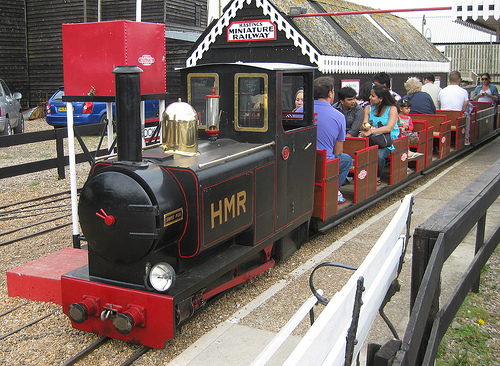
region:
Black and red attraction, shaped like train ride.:
[15, 0, 497, 339]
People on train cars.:
[312, 74, 499, 214]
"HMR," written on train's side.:
[191, 166, 279, 251]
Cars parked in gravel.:
[0, 81, 97, 192]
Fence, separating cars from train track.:
[0, 118, 166, 180]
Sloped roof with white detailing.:
[257, 0, 457, 84]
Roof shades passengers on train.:
[262, 0, 468, 208]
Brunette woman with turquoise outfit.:
[367, 81, 400, 155]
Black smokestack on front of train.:
[109, 65, 158, 196]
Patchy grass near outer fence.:
[440, 255, 487, 365]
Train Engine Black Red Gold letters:
[9, 59, 317, 346]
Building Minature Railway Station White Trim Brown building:
[177, 4, 455, 159]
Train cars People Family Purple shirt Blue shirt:
[282, 69, 409, 223]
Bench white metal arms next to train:
[147, 184, 439, 362]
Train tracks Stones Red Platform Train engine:
[2, 192, 160, 360]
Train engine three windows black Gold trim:
[173, 49, 324, 253]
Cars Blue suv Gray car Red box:
[0, 52, 181, 153]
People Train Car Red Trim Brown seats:
[393, 64, 498, 171]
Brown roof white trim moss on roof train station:
[267, 2, 459, 74]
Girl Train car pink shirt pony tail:
[349, 64, 463, 182]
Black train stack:
[103, 53, 160, 155]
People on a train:
[301, 55, 496, 149]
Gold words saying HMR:
[200, 177, 257, 232]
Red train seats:
[310, 112, 476, 217]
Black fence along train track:
[402, 157, 497, 354]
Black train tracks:
[0, 180, 85, 365]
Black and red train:
[66, 62, 316, 362]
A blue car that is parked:
[41, 80, 118, 140]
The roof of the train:
[160, 0, 460, 70]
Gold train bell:
[153, 93, 208, 158]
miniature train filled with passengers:
[60, 62, 499, 345]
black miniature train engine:
[60, 60, 318, 347]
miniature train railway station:
[182, 2, 452, 102]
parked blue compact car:
[47, 87, 167, 125]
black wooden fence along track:
[375, 157, 499, 364]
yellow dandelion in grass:
[450, 313, 499, 350]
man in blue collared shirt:
[290, 76, 351, 206]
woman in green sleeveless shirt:
[362, 85, 399, 177]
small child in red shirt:
[394, 98, 420, 147]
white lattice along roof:
[187, 0, 454, 70]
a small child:
[396, 102, 411, 127]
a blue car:
[44, 82, 169, 125]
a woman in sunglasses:
[471, 70, 498, 104]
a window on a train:
[235, 76, 267, 128]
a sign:
[225, 20, 281, 40]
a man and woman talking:
[336, 80, 399, 146]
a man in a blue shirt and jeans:
[304, 77, 351, 199]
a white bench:
[248, 202, 418, 364]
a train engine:
[67, 58, 306, 344]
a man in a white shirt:
[441, 69, 471, 139]